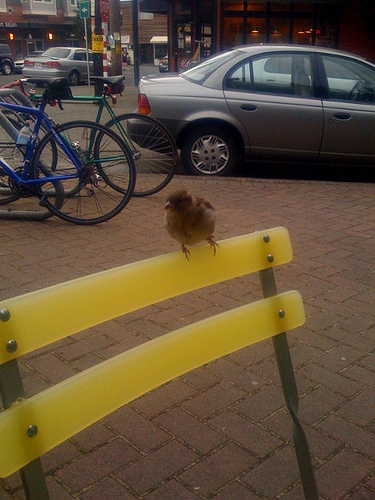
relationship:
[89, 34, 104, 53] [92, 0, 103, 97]
sign on pole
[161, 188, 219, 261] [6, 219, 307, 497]
bird on a bench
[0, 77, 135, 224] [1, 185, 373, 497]
bicycle parked on sidewalk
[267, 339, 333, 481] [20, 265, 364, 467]
black iron back chair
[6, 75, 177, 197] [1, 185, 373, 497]
bicycle on sidewalk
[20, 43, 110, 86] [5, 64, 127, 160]
car on street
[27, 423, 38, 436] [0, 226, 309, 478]
bolt in chair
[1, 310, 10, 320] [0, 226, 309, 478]
screw in chair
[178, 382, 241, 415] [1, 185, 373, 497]
brick on sidewalk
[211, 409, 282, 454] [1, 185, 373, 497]
brick on sidewalk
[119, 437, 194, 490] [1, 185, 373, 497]
brick on sidewalk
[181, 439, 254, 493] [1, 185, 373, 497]
brick on sidewalk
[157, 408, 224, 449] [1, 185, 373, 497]
brick on sidewalk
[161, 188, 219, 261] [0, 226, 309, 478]
bird on chair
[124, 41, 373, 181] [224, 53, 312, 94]
car has window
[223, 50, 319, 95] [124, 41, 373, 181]
window on car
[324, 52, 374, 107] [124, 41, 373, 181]
window on car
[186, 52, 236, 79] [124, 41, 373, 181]
window on car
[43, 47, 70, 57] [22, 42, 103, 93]
window on car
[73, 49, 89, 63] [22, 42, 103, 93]
window on car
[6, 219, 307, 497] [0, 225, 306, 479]
bench has top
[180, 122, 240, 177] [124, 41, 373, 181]
back tire of car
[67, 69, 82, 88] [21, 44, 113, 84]
back tire of car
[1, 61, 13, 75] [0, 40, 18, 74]
back tire of car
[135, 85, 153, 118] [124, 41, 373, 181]
tail light of car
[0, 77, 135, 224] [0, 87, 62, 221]
bicycle parked at bike rack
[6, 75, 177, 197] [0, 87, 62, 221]
bicycle parked at bike rack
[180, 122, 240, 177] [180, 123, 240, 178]
back tire on tire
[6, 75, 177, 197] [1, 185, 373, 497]
bicycle parked on sidewalk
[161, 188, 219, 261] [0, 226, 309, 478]
bird perched on chair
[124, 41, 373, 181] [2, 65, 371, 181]
car on street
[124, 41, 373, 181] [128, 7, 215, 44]
car in background